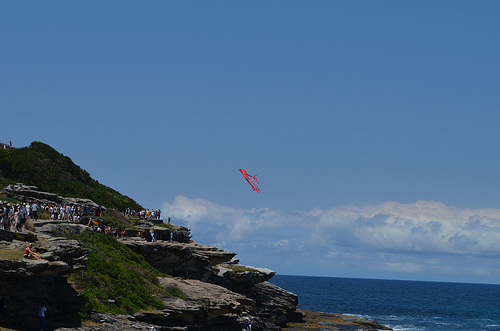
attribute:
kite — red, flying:
[234, 166, 263, 194]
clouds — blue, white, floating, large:
[168, 198, 480, 252]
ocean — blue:
[283, 275, 496, 329]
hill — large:
[2, 143, 279, 330]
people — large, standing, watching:
[2, 197, 163, 232]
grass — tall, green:
[81, 238, 148, 305]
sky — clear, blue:
[5, 10, 492, 171]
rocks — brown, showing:
[151, 239, 270, 305]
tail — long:
[246, 175, 259, 193]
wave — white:
[337, 309, 437, 330]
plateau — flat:
[299, 310, 372, 329]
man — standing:
[35, 301, 51, 322]